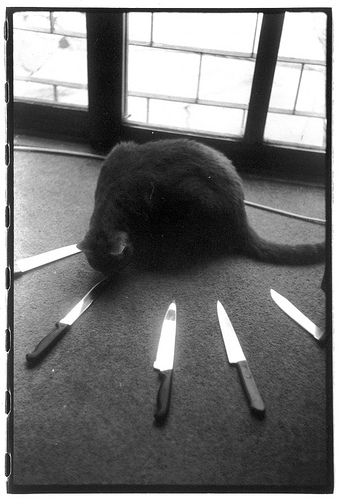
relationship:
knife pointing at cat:
[27, 275, 117, 363] [76, 139, 326, 277]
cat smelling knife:
[76, 139, 326, 277] [27, 275, 117, 363]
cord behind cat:
[14, 144, 325, 223] [76, 139, 326, 277]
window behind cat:
[12, 10, 327, 191] [76, 139, 326, 277]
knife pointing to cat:
[11, 241, 81, 275] [76, 139, 326, 277]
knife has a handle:
[27, 275, 117, 363] [26, 322, 73, 362]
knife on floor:
[153, 298, 178, 423] [14, 131, 327, 485]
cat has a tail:
[76, 139, 326, 277] [236, 218, 326, 267]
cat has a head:
[76, 139, 326, 277] [76, 226, 135, 278]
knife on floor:
[216, 298, 265, 415] [14, 131, 327, 485]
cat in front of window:
[76, 139, 326, 277] [12, 10, 327, 191]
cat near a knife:
[76, 139, 326, 277] [27, 275, 117, 363]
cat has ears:
[76, 139, 326, 277] [76, 237, 128, 256]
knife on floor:
[270, 287, 326, 345] [14, 131, 327, 485]